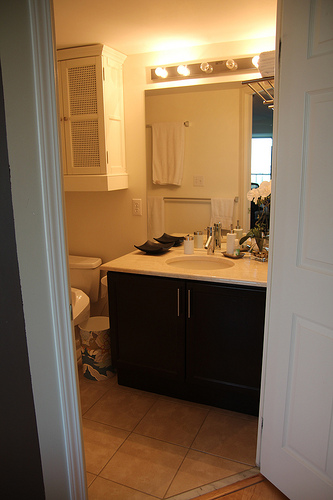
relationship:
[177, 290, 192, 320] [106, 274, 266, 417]
handles on cabinet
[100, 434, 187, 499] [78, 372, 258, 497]
tile on floor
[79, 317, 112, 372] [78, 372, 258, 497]
trashcan on floor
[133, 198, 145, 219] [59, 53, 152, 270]
outlet on wall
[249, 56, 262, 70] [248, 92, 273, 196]
light bulb above mirror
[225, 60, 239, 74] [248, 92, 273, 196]
light bulb above mirror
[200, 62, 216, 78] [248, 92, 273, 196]
light bulb above mirror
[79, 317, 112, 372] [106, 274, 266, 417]
trashcan by cabinet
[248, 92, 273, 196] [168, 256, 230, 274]
mirror above sink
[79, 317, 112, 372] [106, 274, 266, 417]
trashcan next to cabinet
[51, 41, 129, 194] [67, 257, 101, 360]
cabinet above toilet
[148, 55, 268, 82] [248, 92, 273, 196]
light fixture above mirror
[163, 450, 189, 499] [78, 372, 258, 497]
groutline on floor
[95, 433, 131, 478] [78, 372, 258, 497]
groutline on floor